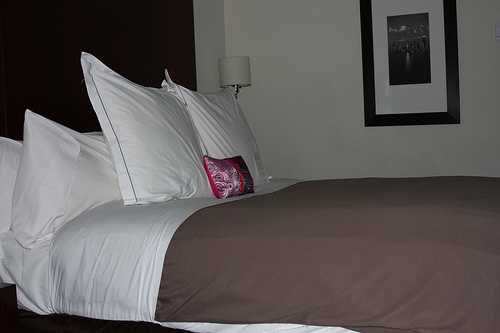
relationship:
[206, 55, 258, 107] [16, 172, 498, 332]
lamp beside bed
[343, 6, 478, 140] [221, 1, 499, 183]
picture on wall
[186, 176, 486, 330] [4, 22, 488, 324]
comforter on bed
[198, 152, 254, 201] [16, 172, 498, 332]
pillow on bed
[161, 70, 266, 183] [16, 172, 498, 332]
pillow on bed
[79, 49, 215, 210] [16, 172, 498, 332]
pillow on bed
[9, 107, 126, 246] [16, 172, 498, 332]
pillow on bed